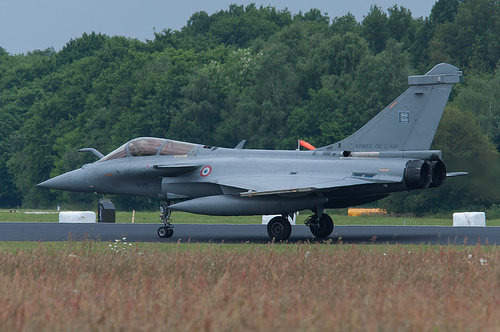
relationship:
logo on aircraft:
[200, 164, 213, 177] [34, 61, 469, 241]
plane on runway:
[34, 61, 469, 241] [0, 222, 499, 247]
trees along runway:
[0, 1, 499, 219] [0, 222, 499, 247]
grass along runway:
[1, 208, 499, 230] [0, 222, 499, 247]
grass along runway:
[0, 243, 498, 331] [0, 222, 499, 247]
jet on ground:
[34, 61, 469, 241] [0, 222, 499, 247]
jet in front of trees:
[34, 61, 469, 241] [0, 1, 499, 219]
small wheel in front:
[155, 220, 175, 240] [34, 127, 250, 239]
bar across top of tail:
[406, 72, 463, 86] [385, 60, 466, 110]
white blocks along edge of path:
[56, 207, 99, 227] [0, 219, 498, 230]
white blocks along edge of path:
[259, 209, 299, 226] [0, 219, 498, 230]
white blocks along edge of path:
[450, 210, 486, 229] [0, 219, 498, 230]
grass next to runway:
[1, 208, 499, 230] [0, 222, 499, 247]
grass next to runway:
[0, 243, 498, 331] [0, 222, 499, 247]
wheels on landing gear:
[308, 212, 337, 240] [309, 204, 328, 222]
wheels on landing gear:
[266, 215, 294, 241] [268, 209, 294, 221]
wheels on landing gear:
[155, 220, 175, 240] [157, 199, 174, 231]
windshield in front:
[93, 134, 210, 163] [34, 127, 250, 239]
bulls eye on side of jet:
[200, 164, 213, 177] [33, 151, 417, 198]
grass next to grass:
[2, 255, 496, 331] [1, 240, 498, 254]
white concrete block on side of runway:
[56, 207, 99, 227] [0, 222, 499, 247]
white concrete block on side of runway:
[259, 209, 299, 226] [0, 222, 499, 247]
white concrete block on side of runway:
[450, 210, 486, 229] [0, 222, 499, 247]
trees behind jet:
[0, 1, 499, 219] [34, 61, 469, 241]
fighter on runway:
[34, 61, 469, 241] [0, 222, 499, 247]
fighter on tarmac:
[34, 61, 469, 241] [0, 222, 499, 247]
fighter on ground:
[34, 61, 469, 241] [0, 222, 499, 247]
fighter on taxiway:
[34, 61, 469, 241] [0, 222, 499, 247]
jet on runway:
[34, 61, 469, 241] [0, 222, 499, 247]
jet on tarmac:
[34, 61, 469, 241] [0, 222, 499, 247]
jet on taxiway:
[34, 61, 469, 241] [0, 222, 499, 247]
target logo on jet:
[200, 164, 213, 177] [34, 61, 469, 241]